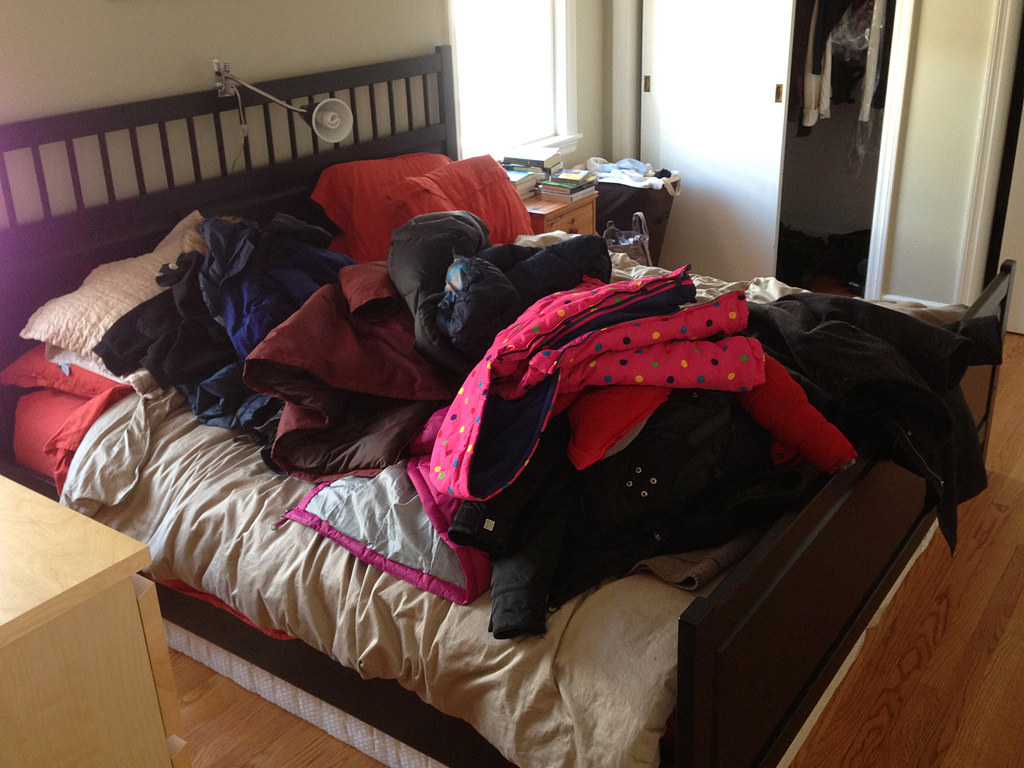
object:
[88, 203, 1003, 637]
jackets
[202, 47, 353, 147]
lamp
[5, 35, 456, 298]
headboard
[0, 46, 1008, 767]
bed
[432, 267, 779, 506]
coat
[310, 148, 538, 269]
pillow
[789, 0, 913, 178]
clothes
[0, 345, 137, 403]
pillow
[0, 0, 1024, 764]
bedroom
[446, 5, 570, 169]
window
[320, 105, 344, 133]
light bulb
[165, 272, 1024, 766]
floor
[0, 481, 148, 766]
dresser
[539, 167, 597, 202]
books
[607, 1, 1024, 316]
closet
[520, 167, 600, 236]
dresser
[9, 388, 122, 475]
sheets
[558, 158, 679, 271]
laundry hamper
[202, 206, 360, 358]
coat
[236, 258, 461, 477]
jacket